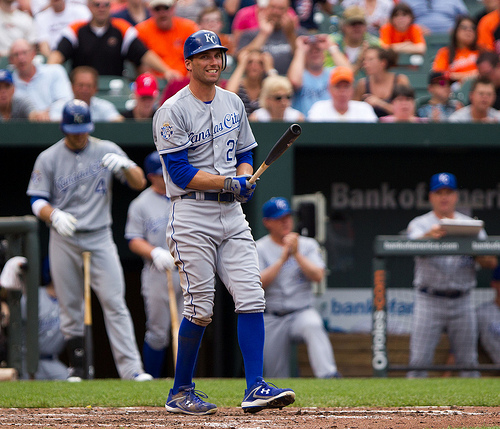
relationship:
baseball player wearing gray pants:
[150, 27, 297, 414] [156, 192, 277, 322]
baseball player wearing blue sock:
[150, 27, 297, 414] [172, 317, 207, 395]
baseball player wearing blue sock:
[150, 27, 297, 414] [237, 308, 266, 389]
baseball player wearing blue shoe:
[150, 27, 297, 414] [162, 386, 218, 416]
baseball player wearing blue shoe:
[150, 27, 297, 414] [234, 380, 299, 414]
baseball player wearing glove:
[150, 27, 297, 414] [218, 172, 254, 199]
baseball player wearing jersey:
[150, 27, 297, 414] [152, 84, 260, 197]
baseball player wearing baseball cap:
[150, 27, 297, 414] [184, 30, 229, 72]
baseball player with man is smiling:
[150, 27, 297, 414] [194, 51, 223, 82]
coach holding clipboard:
[406, 172, 497, 378] [429, 218, 484, 237]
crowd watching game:
[3, 1, 499, 126] [8, 121, 493, 424]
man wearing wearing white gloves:
[30, 102, 147, 382] [51, 151, 128, 238]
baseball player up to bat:
[150, 27, 297, 414] [239, 105, 337, 184]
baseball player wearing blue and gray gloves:
[150, 27, 297, 414] [222, 174, 260, 203]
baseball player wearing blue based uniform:
[150, 27, 297, 414] [150, 85, 296, 384]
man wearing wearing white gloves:
[27, 99, 156, 380] [33, 148, 134, 236]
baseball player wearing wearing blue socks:
[150, 27, 297, 414] [138, 335, 167, 375]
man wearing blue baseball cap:
[27, 99, 156, 380] [260, 196, 290, 218]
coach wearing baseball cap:
[406, 170, 497, 378] [429, 172, 457, 191]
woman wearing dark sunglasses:
[258, 75, 301, 118] [90, 0, 116, 13]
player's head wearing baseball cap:
[177, 28, 240, 84] [62, 99, 96, 135]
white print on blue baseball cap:
[205, 34, 216, 43] [260, 196, 290, 218]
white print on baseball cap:
[204, 33, 216, 44] [62, 99, 96, 135]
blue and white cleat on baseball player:
[235, 366, 298, 416] [150, 23, 300, 425]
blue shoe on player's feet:
[234, 380, 299, 414] [160, 381, 220, 422]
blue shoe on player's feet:
[162, 386, 218, 416] [237, 379, 297, 419]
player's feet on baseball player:
[237, 379, 297, 419] [150, 27, 297, 414]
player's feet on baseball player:
[160, 381, 220, 422] [150, 27, 297, 414]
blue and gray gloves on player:
[217, 169, 269, 205] [157, 17, 304, 424]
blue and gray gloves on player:
[222, 174, 260, 203] [157, 17, 304, 424]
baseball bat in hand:
[233, 110, 305, 199] [222, 170, 247, 197]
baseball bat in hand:
[233, 110, 305, 199] [240, 173, 256, 200]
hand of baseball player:
[222, 170, 247, 197] [150, 27, 297, 414]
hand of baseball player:
[240, 173, 256, 200] [150, 27, 297, 414]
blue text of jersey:
[189, 105, 252, 158] [142, 77, 258, 197]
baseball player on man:
[150, 27, 297, 414] [27, 99, 156, 380]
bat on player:
[75, 242, 96, 382] [124, 146, 191, 375]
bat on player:
[164, 262, 184, 371] [157, 26, 289, 411]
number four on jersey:
[89, 171, 119, 206] [27, 133, 132, 238]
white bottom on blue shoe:
[238, 390, 292, 410] [234, 380, 299, 414]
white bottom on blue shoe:
[160, 404, 200, 418] [162, 386, 220, 424]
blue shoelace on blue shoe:
[257, 366, 290, 389] [234, 380, 299, 414]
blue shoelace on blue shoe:
[173, 386, 213, 402] [162, 386, 218, 416]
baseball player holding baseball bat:
[150, 27, 297, 414] [234, 124, 302, 198]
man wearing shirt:
[381, 1, 428, 54] [381, 21, 426, 48]